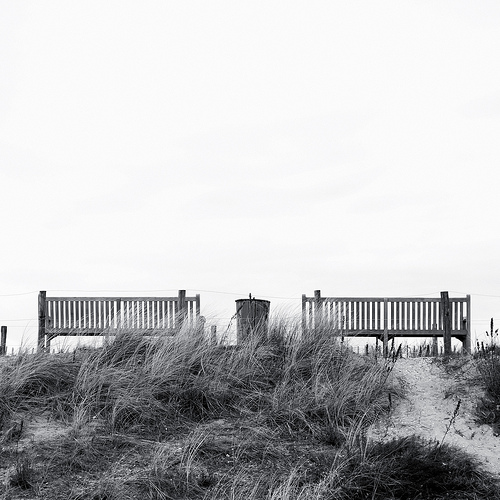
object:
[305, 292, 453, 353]
posts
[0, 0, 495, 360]
sky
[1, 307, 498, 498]
grass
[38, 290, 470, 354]
bench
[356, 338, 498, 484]
dirt path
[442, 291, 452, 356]
post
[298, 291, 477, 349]
bench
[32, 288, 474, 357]
weeds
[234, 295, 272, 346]
trash can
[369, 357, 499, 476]
sand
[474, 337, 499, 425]
bush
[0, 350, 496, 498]
beach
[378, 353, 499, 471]
patch area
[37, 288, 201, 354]
fence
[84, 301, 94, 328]
vertical line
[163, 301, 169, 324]
vertical line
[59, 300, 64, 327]
vertical line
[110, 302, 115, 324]
vertical line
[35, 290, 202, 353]
bench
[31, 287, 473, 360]
benches